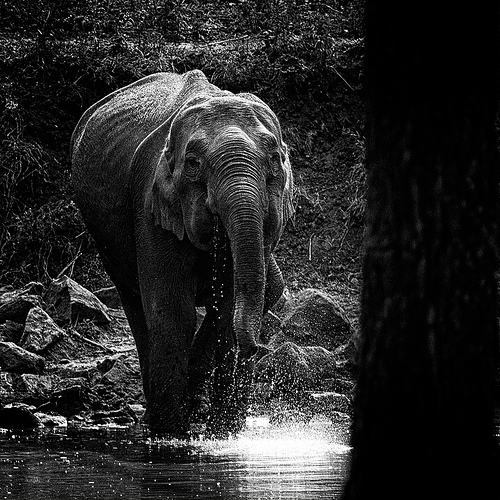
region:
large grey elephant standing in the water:
[60, 62, 300, 439]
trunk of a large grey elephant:
[205, 160, 282, 357]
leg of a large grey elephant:
[135, 230, 206, 442]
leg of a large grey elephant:
[262, 250, 284, 319]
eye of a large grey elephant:
[266, 147, 287, 176]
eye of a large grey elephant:
[182, 149, 204, 177]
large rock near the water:
[275, 281, 354, 350]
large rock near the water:
[43, 273, 115, 330]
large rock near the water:
[17, 299, 73, 359]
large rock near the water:
[0, 335, 53, 380]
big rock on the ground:
[15, 268, 129, 441]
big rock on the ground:
[19, 258, 118, 426]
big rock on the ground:
[12, 252, 92, 426]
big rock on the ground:
[1, 251, 93, 405]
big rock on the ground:
[4, 261, 98, 431]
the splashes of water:
[221, 384, 296, 463]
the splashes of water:
[209, 389, 339, 466]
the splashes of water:
[196, 376, 304, 463]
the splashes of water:
[217, 377, 337, 475]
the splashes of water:
[200, 367, 335, 478]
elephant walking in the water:
[51, 55, 328, 448]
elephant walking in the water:
[59, 74, 311, 479]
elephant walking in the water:
[68, 67, 339, 497]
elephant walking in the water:
[47, 59, 282, 496]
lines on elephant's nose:
[200, 142, 295, 396]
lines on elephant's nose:
[200, 157, 272, 401]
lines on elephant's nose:
[210, 146, 302, 430]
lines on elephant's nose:
[206, 142, 287, 394]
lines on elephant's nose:
[197, 172, 328, 467]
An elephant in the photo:
[57, 57, 302, 438]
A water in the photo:
[211, 431, 315, 496]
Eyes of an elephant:
[171, 150, 292, 190]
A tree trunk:
[380, 65, 460, 303]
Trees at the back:
[284, 32, 343, 143]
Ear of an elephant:
[147, 139, 184, 224]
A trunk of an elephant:
[227, 248, 267, 353]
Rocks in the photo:
[305, 299, 341, 384]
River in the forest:
[270, 379, 335, 481]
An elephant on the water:
[52, 62, 332, 367]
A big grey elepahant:
[70, 80, 325, 337]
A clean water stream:
[20, 432, 82, 498]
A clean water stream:
[79, 443, 183, 498]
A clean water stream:
[205, 444, 317, 498]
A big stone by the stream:
[288, 277, 345, 337]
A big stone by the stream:
[57, 350, 125, 380]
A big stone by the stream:
[22, 306, 77, 355]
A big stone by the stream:
[1, 271, 40, 305]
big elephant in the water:
[79, 86, 292, 349]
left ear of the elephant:
[286, 188, 293, 221]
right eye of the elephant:
[183, 152, 203, 170]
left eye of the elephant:
[268, 150, 282, 163]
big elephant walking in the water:
[91, 105, 286, 435]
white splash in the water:
[203, 422, 318, 459]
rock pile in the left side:
[14, 289, 91, 359]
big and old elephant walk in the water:
[81, 98, 281, 270]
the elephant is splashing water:
[68, 62, 350, 474]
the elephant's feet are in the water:
[78, 66, 282, 448]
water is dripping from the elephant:
[202, 222, 276, 445]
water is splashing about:
[161, 375, 351, 463]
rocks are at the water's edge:
[3, 276, 353, 436]